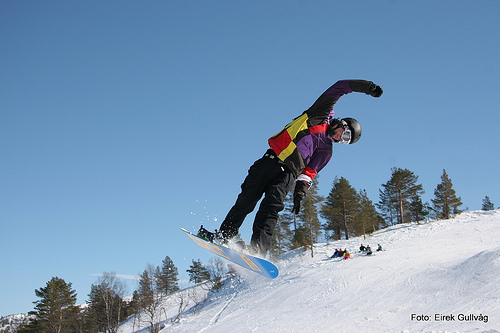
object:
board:
[180, 227, 279, 279]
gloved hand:
[369, 83, 383, 98]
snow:
[96, 207, 498, 331]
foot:
[213, 229, 235, 245]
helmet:
[341, 117, 361, 144]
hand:
[290, 193, 304, 215]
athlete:
[213, 80, 383, 260]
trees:
[381, 166, 426, 223]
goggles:
[338, 120, 352, 144]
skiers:
[376, 244, 382, 252]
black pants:
[219, 149, 297, 256]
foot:
[246, 244, 267, 259]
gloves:
[368, 82, 384, 97]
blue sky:
[1, 0, 498, 314]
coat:
[268, 78, 374, 182]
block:
[268, 128, 291, 156]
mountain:
[0, 208, 500, 332]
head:
[329, 117, 362, 144]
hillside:
[0, 201, 498, 331]